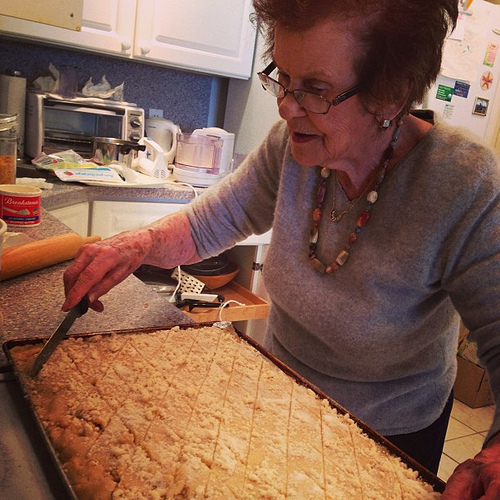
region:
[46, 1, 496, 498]
Old woman in the foreground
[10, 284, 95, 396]
Woman is holding a knife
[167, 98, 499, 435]
Woman is wearing a gray shirt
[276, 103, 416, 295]
Woman is wearing a necklace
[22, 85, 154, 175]
A toaster oven in the background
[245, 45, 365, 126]
Woman is wearing eyeglasses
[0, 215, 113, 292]
A wooden roller in the background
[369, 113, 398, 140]
Woman is wearing an earring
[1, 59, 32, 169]
Paper towels in the background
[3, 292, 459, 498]
Food is in a baking pan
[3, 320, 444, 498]
A dessert on the tray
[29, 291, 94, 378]
A knife in the woman's hand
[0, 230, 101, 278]
A rolling pin on the counter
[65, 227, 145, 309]
The right hand of the woman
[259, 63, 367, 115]
The woman is wearing glasses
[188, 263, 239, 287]
A bowl on the shelf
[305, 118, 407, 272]
The woman is wearing a necklace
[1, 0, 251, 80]
Cabinets above the counter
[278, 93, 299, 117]
The nose of the woman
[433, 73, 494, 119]
Magnets on the refridgerator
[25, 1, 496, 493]
a woman cutting a pastry with a knife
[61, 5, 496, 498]
a woman wearing a gray shirt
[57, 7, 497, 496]
a woman wearing glasses, earrings, and two necklaces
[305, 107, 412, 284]
a necklace made of multi-colored beads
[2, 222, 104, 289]
a rolling pin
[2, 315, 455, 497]
a tray of pastries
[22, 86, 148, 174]
a chrome toaster oven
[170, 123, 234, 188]
a white food processor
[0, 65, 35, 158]
a roll of paper towels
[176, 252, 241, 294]
two bowls on a pullout drawer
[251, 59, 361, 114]
a woman's eyeglasses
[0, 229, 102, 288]
a brown dough roller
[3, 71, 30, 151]
part of a white paper towel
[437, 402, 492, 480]
part of white floor tile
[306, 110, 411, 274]
a woman's necklace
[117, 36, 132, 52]
a white cabinet knob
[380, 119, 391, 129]
a small earring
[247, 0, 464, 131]
part of a woman's hair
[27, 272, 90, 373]
part of a knife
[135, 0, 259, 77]
part of a white cabinet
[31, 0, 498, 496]
woman slicing dessert in her kitchen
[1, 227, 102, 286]
wooden rolling pin on top of the counter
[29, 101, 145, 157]
silver and black toaster oven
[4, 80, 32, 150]
roll of white paper towels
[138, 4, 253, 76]
pretty white cabinets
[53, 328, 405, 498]
diagnoally sliced dessert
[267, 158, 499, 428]
long sleeved gray sweater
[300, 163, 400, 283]
green, brown, and white necklace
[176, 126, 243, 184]
mixer on top of counter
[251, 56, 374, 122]
pair of brown rectangular eyeglasses